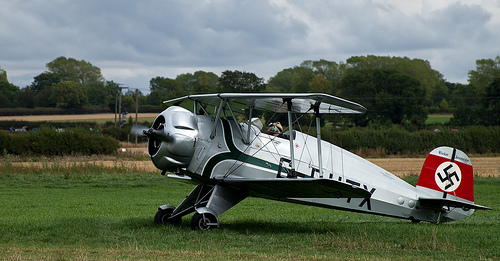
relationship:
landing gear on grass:
[154, 184, 246, 230] [1, 163, 498, 259]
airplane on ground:
[141, 92, 497, 235] [34, 211, 498, 251]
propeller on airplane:
[107, 114, 203, 158] [144, 92, 492, 229]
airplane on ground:
[141, 92, 497, 235] [4, 154, 498, 257]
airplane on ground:
[144, 92, 492, 229] [4, 154, 498, 257]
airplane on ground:
[141, 92, 497, 235] [16, 170, 136, 251]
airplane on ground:
[141, 92, 497, 235] [0, 170, 160, 260]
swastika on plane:
[439, 158, 461, 195] [145, 67, 487, 229]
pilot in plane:
[265, 120, 283, 137] [131, 92, 493, 232]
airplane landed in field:
[141, 92, 497, 235] [6, 156, 498, 254]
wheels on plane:
[153, 198, 215, 233] [131, 92, 493, 232]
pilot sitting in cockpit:
[265, 120, 284, 137] [243, 115, 299, 145]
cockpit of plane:
[243, 115, 299, 145] [131, 92, 493, 232]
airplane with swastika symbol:
[141, 92, 497, 235] [432, 160, 463, 194]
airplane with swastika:
[141, 92, 497, 235] [423, 154, 466, 221]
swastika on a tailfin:
[430, 148, 471, 208] [415, 150, 472, 207]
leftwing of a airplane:
[247, 90, 367, 119] [141, 92, 497, 235]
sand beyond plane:
[0, 158, 499, 178] [131, 92, 493, 232]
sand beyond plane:
[18, 153, 151, 170] [131, 92, 493, 232]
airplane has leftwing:
[141, 92, 497, 235] [213, 177, 373, 200]